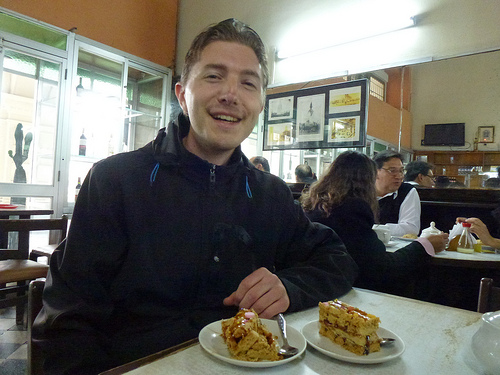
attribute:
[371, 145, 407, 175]
hair — dark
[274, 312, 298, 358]
spoon — silver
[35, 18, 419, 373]
people — getting along well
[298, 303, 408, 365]
plate — oval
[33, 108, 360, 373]
jacket — blue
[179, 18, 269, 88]
hair — light brown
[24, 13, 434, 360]
people — enjoying their day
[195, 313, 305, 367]
plate — oval, white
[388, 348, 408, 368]
plate — oval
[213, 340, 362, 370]
plates — of food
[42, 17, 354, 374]
people —  their lunch break, out in daytime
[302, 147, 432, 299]
people — out in daytime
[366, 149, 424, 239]
people — out in daytime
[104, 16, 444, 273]
people — having a good time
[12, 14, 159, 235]
door — glass